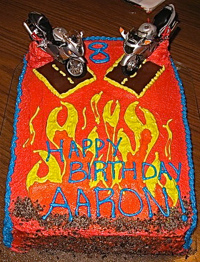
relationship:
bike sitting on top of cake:
[22, 10, 87, 80] [0, 2, 193, 252]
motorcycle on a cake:
[117, 2, 179, 74] [2, 34, 199, 257]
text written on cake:
[41, 136, 188, 221] [2, 34, 199, 257]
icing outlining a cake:
[179, 82, 197, 183] [2, 34, 199, 257]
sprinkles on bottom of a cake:
[55, 218, 146, 230] [2, 34, 199, 257]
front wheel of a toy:
[65, 59, 86, 77] [23, 9, 87, 79]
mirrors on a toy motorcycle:
[116, 25, 151, 49] [117, 2, 179, 74]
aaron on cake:
[43, 186, 171, 221] [2, 34, 199, 257]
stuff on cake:
[12, 203, 190, 256] [2, 34, 199, 257]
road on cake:
[102, 48, 166, 99] [2, 34, 199, 257]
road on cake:
[102, 48, 166, 99] [104, 50, 164, 98]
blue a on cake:
[75, 185, 90, 217] [2, 34, 199, 257]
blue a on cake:
[39, 184, 72, 219] [2, 34, 199, 257]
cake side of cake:
[6, 220, 195, 260] [2, 34, 199, 257]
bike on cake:
[21, 2, 181, 78] [16, 43, 193, 235]